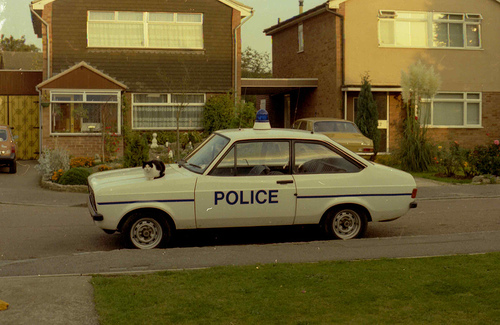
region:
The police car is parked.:
[81, 105, 427, 252]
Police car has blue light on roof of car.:
[80, 101, 427, 251]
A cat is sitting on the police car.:
[80, 101, 427, 251]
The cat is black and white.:
[112, 147, 178, 184]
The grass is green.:
[85, 235, 497, 320]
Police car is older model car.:
[70, 100, 430, 255]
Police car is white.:
[81, 107, 441, 262]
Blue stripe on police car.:
[70, 105, 433, 244]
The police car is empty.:
[71, 98, 431, 253]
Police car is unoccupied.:
[72, 100, 438, 257]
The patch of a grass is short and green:
[111, 275, 491, 318]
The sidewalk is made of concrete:
[73, 238, 490, 267]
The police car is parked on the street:
[87, 106, 421, 250]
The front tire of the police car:
[115, 205, 176, 253]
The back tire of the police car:
[322, 199, 369, 242]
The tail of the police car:
[385, 152, 421, 234]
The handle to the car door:
[270, 177, 300, 187]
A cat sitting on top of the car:
[134, 147, 172, 190]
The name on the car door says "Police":
[209, 186, 281, 207]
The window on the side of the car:
[213, 141, 291, 173]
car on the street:
[86, 89, 416, 236]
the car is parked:
[70, 107, 450, 257]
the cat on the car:
[120, 143, 170, 182]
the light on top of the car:
[253, 105, 290, 133]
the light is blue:
[249, 109, 286, 131]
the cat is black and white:
[135, 152, 171, 181]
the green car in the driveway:
[276, 113, 383, 163]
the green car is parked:
[278, 104, 383, 164]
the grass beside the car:
[114, 250, 494, 320]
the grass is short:
[147, 275, 430, 316]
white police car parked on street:
[97, 114, 418, 239]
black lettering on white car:
[209, 183, 280, 208]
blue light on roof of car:
[250, 109, 272, 129]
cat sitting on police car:
[134, 151, 165, 176]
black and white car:
[140, 154, 164, 184]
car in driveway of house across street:
[279, 104, 382, 161]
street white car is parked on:
[1, 182, 486, 257]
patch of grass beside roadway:
[91, 259, 495, 321]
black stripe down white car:
[96, 191, 411, 207]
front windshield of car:
[185, 138, 235, 168]